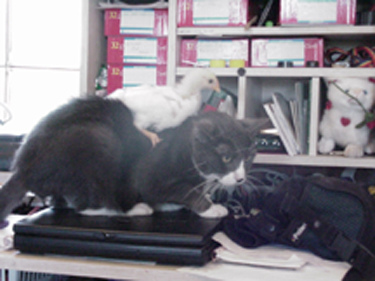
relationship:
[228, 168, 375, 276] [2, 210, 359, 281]
backpack on table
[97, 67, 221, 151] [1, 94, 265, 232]
duck on back of cat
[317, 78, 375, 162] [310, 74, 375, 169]
bear on shelf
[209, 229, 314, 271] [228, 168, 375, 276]
notebook under backpack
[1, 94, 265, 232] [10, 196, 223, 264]
cat on laptop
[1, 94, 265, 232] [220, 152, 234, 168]
cat has eye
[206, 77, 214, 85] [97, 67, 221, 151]
eye of duck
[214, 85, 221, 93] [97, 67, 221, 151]
beak of duck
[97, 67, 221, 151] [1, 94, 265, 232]
duck atop cat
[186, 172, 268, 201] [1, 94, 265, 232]
whiskers on cat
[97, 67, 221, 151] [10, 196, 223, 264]
duck on laptop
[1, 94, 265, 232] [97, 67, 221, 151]
cat carrying duck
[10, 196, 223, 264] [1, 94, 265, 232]
laptop beneath cat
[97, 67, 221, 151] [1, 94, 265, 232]
duck on cat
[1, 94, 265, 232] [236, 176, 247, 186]
cat has nose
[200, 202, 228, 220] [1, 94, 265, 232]
feet of cat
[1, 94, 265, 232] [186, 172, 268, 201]
cat with whiskers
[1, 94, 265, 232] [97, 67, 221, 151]
cat with duck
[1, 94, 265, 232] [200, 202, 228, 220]
cat with feet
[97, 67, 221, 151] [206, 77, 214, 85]
duck with eye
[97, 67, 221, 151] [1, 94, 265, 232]
duck riding cat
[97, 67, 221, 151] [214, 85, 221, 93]
duck with beak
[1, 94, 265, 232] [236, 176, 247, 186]
cat with nose